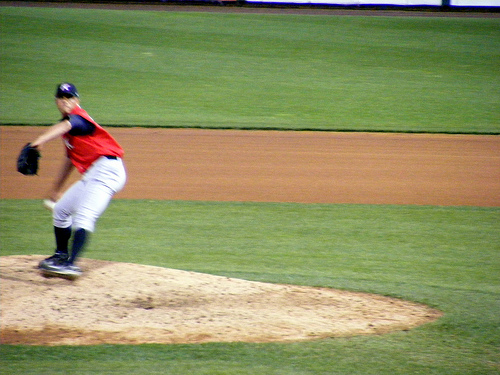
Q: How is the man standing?
A: Somewhat bent backwards.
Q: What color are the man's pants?
A: White.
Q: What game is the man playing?
A: Baseball.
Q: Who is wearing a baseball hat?
A: The baseball player.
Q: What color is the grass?
A: Green.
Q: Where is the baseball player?
A: On the pitcher's mound.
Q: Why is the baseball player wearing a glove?
A: To catch a baseball.